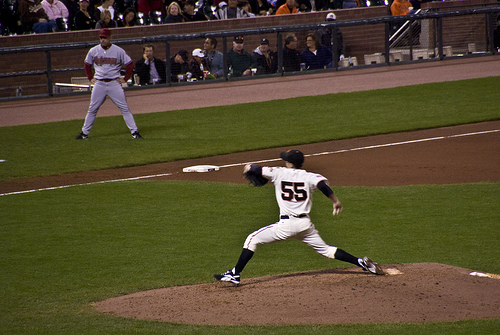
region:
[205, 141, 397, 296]
man on pitching mound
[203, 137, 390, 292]
man throwing a baseball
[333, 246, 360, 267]
black baseball socks on man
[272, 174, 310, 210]
number on top of jersey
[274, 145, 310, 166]
black baseball hat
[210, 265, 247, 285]
black and white cleats on feet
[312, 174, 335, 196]
black long sleeve under shirt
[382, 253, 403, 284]
white top of pitchers mound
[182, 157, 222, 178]
white base on dirt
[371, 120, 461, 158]
white chalk line across field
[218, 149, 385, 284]
a baseball player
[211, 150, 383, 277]
the pitcher on the baseball field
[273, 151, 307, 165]
the hat of the man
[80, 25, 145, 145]
a baseball player standing at a base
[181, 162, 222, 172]
the plate on the field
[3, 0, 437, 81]
people sitting and watching the baseball game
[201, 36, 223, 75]
a man wearing a grey shirt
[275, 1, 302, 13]
a person wearing an orange shirt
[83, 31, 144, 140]
a man wearing a red cap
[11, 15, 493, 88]
a black fence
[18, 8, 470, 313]
a major league baseball game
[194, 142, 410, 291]
a pitcher about to pitch the ball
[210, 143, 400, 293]
a major league baseball player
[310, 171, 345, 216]
the pitching arm of a baseball player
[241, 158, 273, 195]
the arm of a baseball player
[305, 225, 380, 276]
the leg of a baseball player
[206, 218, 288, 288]
the leg of a baseball player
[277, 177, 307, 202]
numbers on the back of a jersey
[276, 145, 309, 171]
a black baseball cap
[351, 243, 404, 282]
the foot of the pitcher on the pitcher's mound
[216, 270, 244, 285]
a snicker of a base ball player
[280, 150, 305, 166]
head cap of a base ball player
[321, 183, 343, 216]
a hand of the base ball player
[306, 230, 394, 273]
the leg of a base ball player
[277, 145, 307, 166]
the head of the base ball player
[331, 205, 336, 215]
fingers of a base ball player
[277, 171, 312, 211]
the back of a base ball player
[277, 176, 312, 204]
a label "55" on the base ball player's kit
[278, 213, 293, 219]
waist belt of the base ball player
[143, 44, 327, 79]
spectators spectating the base ball game